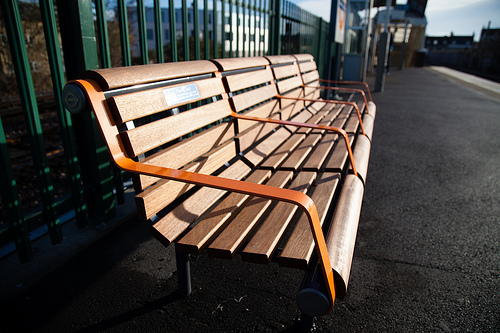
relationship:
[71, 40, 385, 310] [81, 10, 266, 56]
bench in front of fence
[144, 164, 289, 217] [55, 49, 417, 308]
arm rest on bench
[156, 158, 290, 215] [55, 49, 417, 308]
arm rest on bench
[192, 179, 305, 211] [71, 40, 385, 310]
arm rest on bench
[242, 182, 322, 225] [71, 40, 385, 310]
arm rest on bench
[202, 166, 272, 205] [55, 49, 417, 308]
arm rest on bench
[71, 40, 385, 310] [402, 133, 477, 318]
bench on sidewalk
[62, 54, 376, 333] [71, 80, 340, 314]
bench has arm rest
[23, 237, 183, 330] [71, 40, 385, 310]
shadow of bench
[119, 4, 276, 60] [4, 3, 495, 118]
building in background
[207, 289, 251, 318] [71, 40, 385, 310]
cigarette butts under bench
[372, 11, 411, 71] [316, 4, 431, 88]
opening to train station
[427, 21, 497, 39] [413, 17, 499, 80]
tops of buildings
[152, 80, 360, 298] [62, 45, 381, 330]
chair arms on bench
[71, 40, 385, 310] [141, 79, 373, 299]
bench has arms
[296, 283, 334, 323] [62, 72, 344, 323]
end cap on end of arm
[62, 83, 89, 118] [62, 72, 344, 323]
end cap on end of arm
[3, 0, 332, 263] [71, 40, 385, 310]
fencing slats behind bench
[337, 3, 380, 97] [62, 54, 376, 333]
phone booth beyond end of bench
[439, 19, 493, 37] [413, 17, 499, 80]
chimneys on buildings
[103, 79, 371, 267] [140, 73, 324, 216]
arms cast shadows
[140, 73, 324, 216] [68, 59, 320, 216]
shadows on back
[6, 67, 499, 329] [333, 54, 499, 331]
pavement on sidewalk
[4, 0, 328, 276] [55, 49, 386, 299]
fence behind benches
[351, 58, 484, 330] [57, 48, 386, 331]
sidewalk in front of benches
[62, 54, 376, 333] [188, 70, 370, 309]
bench in a row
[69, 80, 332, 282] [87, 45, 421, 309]
arm rest of benches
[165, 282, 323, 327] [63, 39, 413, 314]
feet of benches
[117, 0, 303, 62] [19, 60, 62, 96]
building behind fence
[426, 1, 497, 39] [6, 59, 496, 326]
sky above street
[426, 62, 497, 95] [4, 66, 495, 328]
curb along road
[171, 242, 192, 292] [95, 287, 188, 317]
pole has shadow